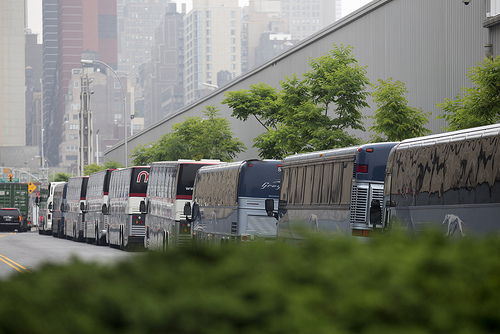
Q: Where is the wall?
A: On the bus side.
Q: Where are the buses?
A: They are packed.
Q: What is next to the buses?
A: Green trees.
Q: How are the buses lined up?
A: In a straight line.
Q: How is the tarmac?
A: Grey.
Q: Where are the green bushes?
A: On the buses side.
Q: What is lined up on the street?
A: Buses.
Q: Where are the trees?
A: Right of the busses.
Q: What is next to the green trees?
A: A wall.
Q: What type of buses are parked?
A: Greyhound buses.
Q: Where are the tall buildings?
A: On the right.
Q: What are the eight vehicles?
A: Greyhound buses.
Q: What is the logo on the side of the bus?
A: A Greyhound picture.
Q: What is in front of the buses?
A: A city.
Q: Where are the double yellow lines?
A: On the road.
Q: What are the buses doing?
A: Parking.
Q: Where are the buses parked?
A: On the side of the road.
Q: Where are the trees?
A: On the side of the buses.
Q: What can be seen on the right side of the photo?
A: Buses.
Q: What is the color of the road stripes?
A: Yellow.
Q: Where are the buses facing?
A: Toward the city.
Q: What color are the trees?
A: Green.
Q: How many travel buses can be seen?
A: Nine.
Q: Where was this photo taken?
A: On a street.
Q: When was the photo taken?
A: Daytime.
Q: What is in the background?
A: Buildings.